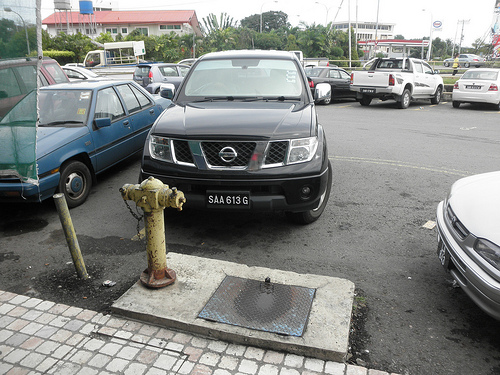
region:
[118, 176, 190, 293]
the yellow fire hydrant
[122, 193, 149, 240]
the chain on the hydrant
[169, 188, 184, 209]
the cap on the fire hydrant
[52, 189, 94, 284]
the pole tilting over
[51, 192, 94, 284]
the yellow pole in the ground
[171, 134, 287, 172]
the grill on the front of the car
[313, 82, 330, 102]
the sideview mirror on the truck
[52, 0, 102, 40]
the water towers behind the parking lot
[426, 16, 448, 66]
the gas station sign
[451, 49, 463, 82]
the person running by the road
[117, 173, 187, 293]
Hydrant in the ground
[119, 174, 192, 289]
Hydrant is in the ground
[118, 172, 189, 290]
Fire hydrant in the ground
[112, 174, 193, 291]
Fire hydrant is in the ground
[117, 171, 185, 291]
Yellow hydrant in the ground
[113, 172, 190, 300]
Yellow hydrant is in the ground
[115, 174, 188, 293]
Yellow fire hydrant in the ground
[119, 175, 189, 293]
Yellow fire hydrant is in the ground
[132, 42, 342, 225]
Black car is parked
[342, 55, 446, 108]
White truck is parked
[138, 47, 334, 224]
parked black vehicle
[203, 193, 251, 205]
license plater on a vehicle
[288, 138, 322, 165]
white car light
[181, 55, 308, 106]
windshield of a black vehicle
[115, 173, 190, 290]
yellow fire hydrant on a parking lot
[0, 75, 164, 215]
parked blue vehicle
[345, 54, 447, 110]
parked white vehicle on a lot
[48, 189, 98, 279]
yellow pole on a parking lot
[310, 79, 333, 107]
rearview mirror of a vehicle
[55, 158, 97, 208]
black wheel of a vehicle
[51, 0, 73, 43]
gray water tank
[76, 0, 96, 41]
light blue water tank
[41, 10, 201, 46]
building with a red roof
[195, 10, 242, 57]
tropical tree in the distance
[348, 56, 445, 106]
white pickup truck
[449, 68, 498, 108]
white sedan in a parking lot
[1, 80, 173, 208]
light blue sedan in a parking lot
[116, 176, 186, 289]
yellow hydrant with chipped paint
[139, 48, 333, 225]
black pickup parked by a hydrant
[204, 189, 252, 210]
black license plate with white lettering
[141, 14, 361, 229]
Black SUV in a parking lot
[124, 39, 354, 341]
Black SUV in a parking lot near a fire hydrant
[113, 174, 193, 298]
Yellow fire hydrant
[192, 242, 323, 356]
Metal cover over a drain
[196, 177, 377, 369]
Metal cover over a drain in a parking lot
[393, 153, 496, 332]
The front part of a saloon car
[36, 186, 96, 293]
Metal rod protruding out of a parking lot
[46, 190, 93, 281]
Old yellow metal rod protruding out of a parking lot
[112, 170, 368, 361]
Fire hydrant and metal drain cover over a concrete slab.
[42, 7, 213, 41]
House with a red roof.